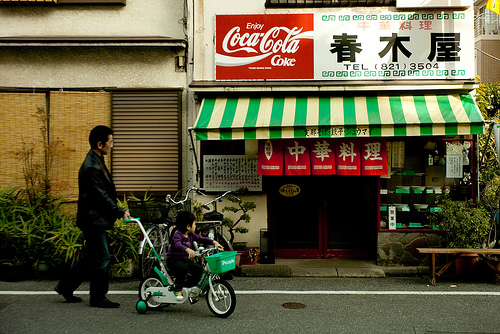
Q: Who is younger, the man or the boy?
A: The boy is younger than the man.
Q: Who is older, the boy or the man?
A: The man is older than the boy.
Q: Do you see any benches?
A: Yes, there is a bench.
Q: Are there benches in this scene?
A: Yes, there is a bench.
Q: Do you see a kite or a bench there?
A: Yes, there is a bench.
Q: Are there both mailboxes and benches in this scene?
A: No, there is a bench but no mailboxes.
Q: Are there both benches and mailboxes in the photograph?
A: No, there is a bench but no mailboxes.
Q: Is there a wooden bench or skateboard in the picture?
A: Yes, there is a wood bench.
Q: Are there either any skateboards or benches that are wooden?
A: Yes, the bench is wooden.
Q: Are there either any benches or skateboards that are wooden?
A: Yes, the bench is wooden.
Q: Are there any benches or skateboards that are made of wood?
A: Yes, the bench is made of wood.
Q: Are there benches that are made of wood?
A: Yes, there is a bench that is made of wood.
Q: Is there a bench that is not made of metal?
A: Yes, there is a bench that is made of wood.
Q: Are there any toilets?
A: No, there are no toilets.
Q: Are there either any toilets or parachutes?
A: No, there are no toilets or parachutes.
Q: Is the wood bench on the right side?
A: Yes, the bench is on the right of the image.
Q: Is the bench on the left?
A: No, the bench is on the right of the image.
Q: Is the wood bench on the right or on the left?
A: The bench is on the right of the image.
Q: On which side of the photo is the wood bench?
A: The bench is on the right of the image.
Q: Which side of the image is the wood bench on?
A: The bench is on the right of the image.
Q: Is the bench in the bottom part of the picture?
A: Yes, the bench is in the bottom of the image.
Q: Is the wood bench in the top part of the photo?
A: No, the bench is in the bottom of the image.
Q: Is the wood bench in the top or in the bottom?
A: The bench is in the bottom of the image.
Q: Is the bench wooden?
A: Yes, the bench is wooden.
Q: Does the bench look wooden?
A: Yes, the bench is wooden.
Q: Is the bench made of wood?
A: Yes, the bench is made of wood.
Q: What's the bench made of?
A: The bench is made of wood.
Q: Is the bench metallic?
A: No, the bench is wooden.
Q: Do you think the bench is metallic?
A: No, the bench is wooden.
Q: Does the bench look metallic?
A: No, the bench is wooden.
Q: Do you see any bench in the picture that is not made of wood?
A: No, there is a bench but it is made of wood.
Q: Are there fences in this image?
A: No, there are no fences.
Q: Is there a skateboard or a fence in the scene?
A: No, there are no fences or skateboards.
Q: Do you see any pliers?
A: No, there are no pliers.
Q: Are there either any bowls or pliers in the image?
A: No, there are no pliers or bowls.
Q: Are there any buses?
A: No, there are no buses.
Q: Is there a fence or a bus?
A: No, there are no buses or fences.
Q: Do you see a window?
A: Yes, there is a window.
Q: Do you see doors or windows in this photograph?
A: Yes, there is a window.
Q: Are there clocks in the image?
A: No, there are no clocks.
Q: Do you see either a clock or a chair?
A: No, there are no clocks or chairs.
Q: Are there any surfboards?
A: No, there are no surfboards.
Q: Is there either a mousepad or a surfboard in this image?
A: No, there are no surfboards or mouse pads.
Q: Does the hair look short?
A: Yes, the hair is short.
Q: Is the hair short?
A: Yes, the hair is short.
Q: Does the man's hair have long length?
A: No, the hair is short.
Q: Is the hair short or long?
A: The hair is short.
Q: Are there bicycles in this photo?
A: Yes, there is a bicycle.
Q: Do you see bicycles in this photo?
A: Yes, there is a bicycle.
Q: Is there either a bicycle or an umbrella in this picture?
A: Yes, there is a bicycle.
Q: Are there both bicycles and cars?
A: No, there is a bicycle but no cars.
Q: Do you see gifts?
A: No, there are no gifts.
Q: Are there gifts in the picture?
A: No, there are no gifts.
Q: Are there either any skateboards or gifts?
A: No, there are no gifts or skateboards.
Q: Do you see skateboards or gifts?
A: No, there are no gifts or skateboards.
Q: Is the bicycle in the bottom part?
A: Yes, the bicycle is in the bottom of the image.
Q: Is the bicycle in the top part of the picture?
A: No, the bicycle is in the bottom of the image.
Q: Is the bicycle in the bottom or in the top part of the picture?
A: The bicycle is in the bottom of the image.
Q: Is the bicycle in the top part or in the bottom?
A: The bicycle is in the bottom of the image.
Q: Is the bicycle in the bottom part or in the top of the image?
A: The bicycle is in the bottom of the image.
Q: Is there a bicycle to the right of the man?
A: Yes, there is a bicycle to the right of the man.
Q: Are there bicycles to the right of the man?
A: Yes, there is a bicycle to the right of the man.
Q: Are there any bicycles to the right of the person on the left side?
A: Yes, there is a bicycle to the right of the man.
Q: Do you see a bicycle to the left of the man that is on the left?
A: No, the bicycle is to the right of the man.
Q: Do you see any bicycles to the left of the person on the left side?
A: No, the bicycle is to the right of the man.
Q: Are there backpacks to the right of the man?
A: No, there is a bicycle to the right of the man.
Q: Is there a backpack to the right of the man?
A: No, there is a bicycle to the right of the man.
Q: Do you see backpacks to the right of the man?
A: No, there is a bicycle to the right of the man.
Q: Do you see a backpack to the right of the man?
A: No, there is a bicycle to the right of the man.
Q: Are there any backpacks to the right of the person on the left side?
A: No, there is a bicycle to the right of the man.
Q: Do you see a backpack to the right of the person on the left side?
A: No, there is a bicycle to the right of the man.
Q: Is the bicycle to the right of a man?
A: Yes, the bicycle is to the right of a man.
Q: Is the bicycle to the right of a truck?
A: No, the bicycle is to the right of a man.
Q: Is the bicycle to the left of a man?
A: No, the bicycle is to the right of a man.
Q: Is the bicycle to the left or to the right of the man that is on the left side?
A: The bicycle is to the right of the man.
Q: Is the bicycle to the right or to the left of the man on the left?
A: The bicycle is to the right of the man.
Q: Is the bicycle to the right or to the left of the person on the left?
A: The bicycle is to the right of the man.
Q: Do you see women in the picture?
A: No, there are no women.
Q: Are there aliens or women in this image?
A: No, there are no women or aliens.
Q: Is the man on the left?
A: Yes, the man is on the left of the image.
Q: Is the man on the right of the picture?
A: No, the man is on the left of the image.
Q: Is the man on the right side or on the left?
A: The man is on the left of the image.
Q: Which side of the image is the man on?
A: The man is on the left of the image.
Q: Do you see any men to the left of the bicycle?
A: Yes, there is a man to the left of the bicycle.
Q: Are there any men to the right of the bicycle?
A: No, the man is to the left of the bicycle.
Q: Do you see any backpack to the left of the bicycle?
A: No, there is a man to the left of the bicycle.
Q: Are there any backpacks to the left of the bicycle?
A: No, there is a man to the left of the bicycle.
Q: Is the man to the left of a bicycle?
A: Yes, the man is to the left of a bicycle.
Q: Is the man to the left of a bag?
A: No, the man is to the left of a bicycle.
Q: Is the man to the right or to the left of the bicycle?
A: The man is to the left of the bicycle.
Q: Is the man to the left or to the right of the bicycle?
A: The man is to the left of the bicycle.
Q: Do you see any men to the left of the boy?
A: Yes, there is a man to the left of the boy.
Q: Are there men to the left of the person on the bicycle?
A: Yes, there is a man to the left of the boy.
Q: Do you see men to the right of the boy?
A: No, the man is to the left of the boy.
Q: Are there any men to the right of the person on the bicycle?
A: No, the man is to the left of the boy.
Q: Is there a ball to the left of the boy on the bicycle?
A: No, there is a man to the left of the boy.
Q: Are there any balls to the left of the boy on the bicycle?
A: No, there is a man to the left of the boy.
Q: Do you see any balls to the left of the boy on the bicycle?
A: No, there is a man to the left of the boy.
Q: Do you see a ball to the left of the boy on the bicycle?
A: No, there is a man to the left of the boy.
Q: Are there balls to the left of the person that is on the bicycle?
A: No, there is a man to the left of the boy.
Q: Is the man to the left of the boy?
A: Yes, the man is to the left of the boy.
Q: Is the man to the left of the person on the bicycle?
A: Yes, the man is to the left of the boy.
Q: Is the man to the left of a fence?
A: No, the man is to the left of the boy.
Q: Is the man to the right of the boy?
A: No, the man is to the left of the boy.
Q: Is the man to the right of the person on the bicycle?
A: No, the man is to the left of the boy.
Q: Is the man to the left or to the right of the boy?
A: The man is to the left of the boy.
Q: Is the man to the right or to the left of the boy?
A: The man is to the left of the boy.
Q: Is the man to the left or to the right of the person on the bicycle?
A: The man is to the left of the boy.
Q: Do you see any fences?
A: No, there are no fences.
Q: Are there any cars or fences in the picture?
A: No, there are no fences or cars.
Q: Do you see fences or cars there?
A: No, there are no fences or cars.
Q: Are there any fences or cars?
A: No, there are no fences or cars.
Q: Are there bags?
A: No, there are no bags.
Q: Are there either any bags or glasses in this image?
A: No, there are no bags or glasses.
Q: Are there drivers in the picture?
A: No, there are no drivers.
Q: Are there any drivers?
A: No, there are no drivers.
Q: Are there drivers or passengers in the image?
A: No, there are no drivers or passengers.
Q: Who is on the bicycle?
A: The boy is on the bicycle.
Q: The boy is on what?
A: The boy is on the bicycle.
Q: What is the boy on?
A: The boy is on the bicycle.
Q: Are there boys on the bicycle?
A: Yes, there is a boy on the bicycle.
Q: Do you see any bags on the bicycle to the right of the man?
A: No, there is a boy on the bicycle.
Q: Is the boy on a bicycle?
A: Yes, the boy is on a bicycle.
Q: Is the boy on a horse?
A: No, the boy is on a bicycle.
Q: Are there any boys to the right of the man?
A: Yes, there is a boy to the right of the man.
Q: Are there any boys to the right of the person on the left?
A: Yes, there is a boy to the right of the man.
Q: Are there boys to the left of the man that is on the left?
A: No, the boy is to the right of the man.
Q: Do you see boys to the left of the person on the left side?
A: No, the boy is to the right of the man.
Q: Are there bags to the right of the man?
A: No, there is a boy to the right of the man.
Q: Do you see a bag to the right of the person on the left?
A: No, there is a boy to the right of the man.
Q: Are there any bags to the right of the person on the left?
A: No, there is a boy to the right of the man.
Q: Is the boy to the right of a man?
A: Yes, the boy is to the right of a man.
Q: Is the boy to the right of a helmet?
A: No, the boy is to the right of a man.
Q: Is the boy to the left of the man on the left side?
A: No, the boy is to the right of the man.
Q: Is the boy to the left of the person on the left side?
A: No, the boy is to the right of the man.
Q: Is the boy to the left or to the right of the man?
A: The boy is to the right of the man.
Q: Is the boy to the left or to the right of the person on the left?
A: The boy is to the right of the man.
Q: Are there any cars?
A: No, there are no cars.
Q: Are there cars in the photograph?
A: No, there are no cars.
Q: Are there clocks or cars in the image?
A: No, there are no cars or clocks.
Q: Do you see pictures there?
A: No, there are no pictures.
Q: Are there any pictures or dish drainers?
A: No, there are no pictures or dish drainers.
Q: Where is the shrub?
A: The shrub is on the roadway.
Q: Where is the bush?
A: The shrub is on the roadway.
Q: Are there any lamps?
A: No, there are no lamps.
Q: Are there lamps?
A: No, there are no lamps.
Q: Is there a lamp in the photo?
A: No, there are no lamps.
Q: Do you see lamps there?
A: No, there are no lamps.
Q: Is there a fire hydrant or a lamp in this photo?
A: No, there are no lamps or fire hydrants.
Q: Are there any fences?
A: No, there are no fences.